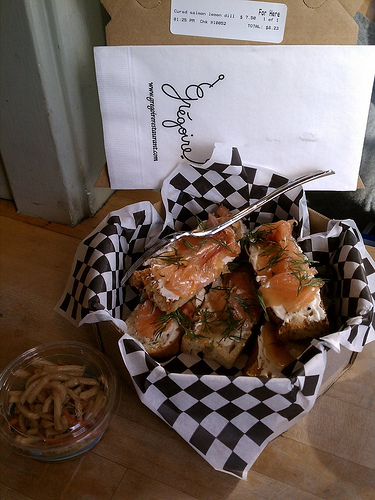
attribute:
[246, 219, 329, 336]
sandwich — sliced, appetizer, salmon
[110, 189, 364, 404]
basket — full of food, lined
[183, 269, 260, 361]
sandwich — sliced, appetizer, salmon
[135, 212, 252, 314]
sandwich — sliced, appetizer, salmon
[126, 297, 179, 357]
sandwich — sliced, appetizer, salmon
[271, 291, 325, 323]
cream cheese — white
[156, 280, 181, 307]
cream cheese — white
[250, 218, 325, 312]
fish — salmon, lox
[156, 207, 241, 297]
fish — salmon, lox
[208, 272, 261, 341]
fish — salmon, lox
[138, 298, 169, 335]
fish — salmon, lox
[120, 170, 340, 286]
spoon — silver, sticking out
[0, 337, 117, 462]
cup — plastic, clear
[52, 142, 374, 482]
napkin — checkered, white, black, checked, paper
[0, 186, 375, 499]
floor — wood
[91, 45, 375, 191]
paper — white, printed, envelope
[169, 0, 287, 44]
label — white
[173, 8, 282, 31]
letters — black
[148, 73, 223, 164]
type — black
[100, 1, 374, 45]
box — to-go box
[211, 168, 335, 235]
handle — silver